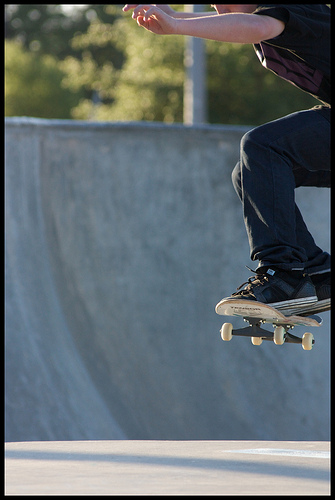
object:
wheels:
[273, 326, 286, 345]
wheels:
[219, 321, 233, 342]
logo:
[254, 34, 322, 94]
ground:
[0, 112, 335, 148]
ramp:
[4, 113, 329, 440]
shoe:
[225, 259, 318, 315]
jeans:
[230, 103, 335, 265]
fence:
[0, 107, 335, 448]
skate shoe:
[297, 272, 333, 316]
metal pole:
[182, 4, 209, 124]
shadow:
[1, 449, 333, 485]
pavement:
[0, 438, 333, 500]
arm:
[121, 5, 285, 44]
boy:
[120, 0, 335, 316]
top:
[250, 30, 315, 79]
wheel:
[251, 335, 263, 346]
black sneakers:
[228, 261, 319, 317]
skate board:
[214, 298, 323, 351]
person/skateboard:
[121, 2, 333, 351]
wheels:
[250, 335, 262, 346]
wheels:
[301, 330, 314, 351]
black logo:
[230, 305, 261, 316]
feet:
[221, 266, 318, 312]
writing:
[230, 307, 261, 311]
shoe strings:
[230, 261, 270, 297]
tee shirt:
[250, 0, 335, 104]